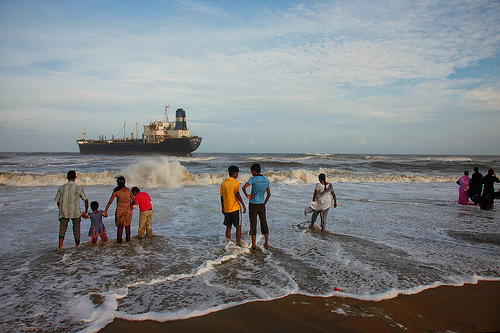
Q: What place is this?
A: It is a shore.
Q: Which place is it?
A: It is a shore.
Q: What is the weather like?
A: It is overcast.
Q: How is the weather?
A: It is overcast.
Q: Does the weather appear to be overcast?
A: Yes, it is overcast.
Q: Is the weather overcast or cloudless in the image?
A: It is overcast.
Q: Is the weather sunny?
A: No, it is overcast.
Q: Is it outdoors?
A: Yes, it is outdoors.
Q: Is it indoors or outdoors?
A: It is outdoors.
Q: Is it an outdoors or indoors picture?
A: It is outdoors.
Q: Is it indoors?
A: No, it is outdoors.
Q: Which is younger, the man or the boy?
A: The boy is younger than the man.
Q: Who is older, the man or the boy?
A: The man is older than the boy.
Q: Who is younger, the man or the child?
A: The child is younger than the man.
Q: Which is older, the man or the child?
A: The man is older than the child.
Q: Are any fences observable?
A: No, there are no fences.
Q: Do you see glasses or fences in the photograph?
A: No, there are no fences or glasses.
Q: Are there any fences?
A: No, there are no fences.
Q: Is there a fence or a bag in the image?
A: No, there are no fences or bags.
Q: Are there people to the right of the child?
A: Yes, there is a person to the right of the child.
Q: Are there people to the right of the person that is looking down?
A: Yes, there is a person to the right of the child.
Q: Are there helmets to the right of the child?
A: No, there is a person to the right of the child.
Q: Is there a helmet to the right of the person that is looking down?
A: No, there is a person to the right of the child.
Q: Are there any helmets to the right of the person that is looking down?
A: No, there is a person to the right of the child.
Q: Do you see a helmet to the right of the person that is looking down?
A: No, there is a person to the right of the child.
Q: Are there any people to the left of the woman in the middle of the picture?
A: Yes, there is a person to the left of the woman.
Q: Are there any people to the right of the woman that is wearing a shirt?
A: No, the person is to the left of the woman.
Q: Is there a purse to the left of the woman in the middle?
A: No, there is a person to the left of the woman.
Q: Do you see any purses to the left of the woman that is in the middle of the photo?
A: No, there is a person to the left of the woman.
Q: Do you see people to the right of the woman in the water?
A: Yes, there is a person to the right of the woman.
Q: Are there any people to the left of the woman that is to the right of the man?
A: No, the person is to the right of the woman.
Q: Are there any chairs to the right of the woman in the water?
A: No, there is a person to the right of the woman.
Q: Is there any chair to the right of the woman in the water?
A: No, there is a person to the right of the woman.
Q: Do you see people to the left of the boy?
A: Yes, there is a person to the left of the boy.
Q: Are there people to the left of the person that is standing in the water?
A: Yes, there is a person to the left of the boy.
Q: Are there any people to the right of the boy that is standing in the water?
A: No, the person is to the left of the boy.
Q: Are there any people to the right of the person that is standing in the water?
A: No, the person is to the left of the boy.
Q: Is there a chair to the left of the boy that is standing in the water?
A: No, there is a person to the left of the boy.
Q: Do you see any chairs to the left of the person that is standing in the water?
A: No, there is a person to the left of the boy.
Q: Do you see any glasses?
A: No, there are no glasses.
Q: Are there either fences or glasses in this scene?
A: No, there are no glasses or fences.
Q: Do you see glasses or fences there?
A: No, there are no glasses or fences.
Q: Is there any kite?
A: No, there are no kites.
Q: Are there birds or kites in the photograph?
A: No, there are no kites or birds.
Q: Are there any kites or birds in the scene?
A: No, there are no kites or birds.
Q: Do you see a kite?
A: No, there are no kites.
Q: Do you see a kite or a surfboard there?
A: No, there are no kites or surfboards.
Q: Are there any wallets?
A: No, there are no wallets.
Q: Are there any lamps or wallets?
A: No, there are no wallets or lamps.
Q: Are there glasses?
A: No, there are no glasses.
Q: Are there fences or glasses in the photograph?
A: No, there are no glasses or fences.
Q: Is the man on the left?
A: Yes, the man is on the left of the image.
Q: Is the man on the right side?
A: No, the man is on the left of the image.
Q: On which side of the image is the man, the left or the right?
A: The man is on the left of the image.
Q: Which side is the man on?
A: The man is on the left of the image.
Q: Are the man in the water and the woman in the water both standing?
A: Yes, both the man and the woman are standing.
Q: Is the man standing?
A: Yes, the man is standing.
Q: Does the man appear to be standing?
A: Yes, the man is standing.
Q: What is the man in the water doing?
A: The man is standing.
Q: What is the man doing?
A: The man is standing.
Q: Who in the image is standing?
A: The man is standing.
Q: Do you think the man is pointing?
A: No, the man is standing.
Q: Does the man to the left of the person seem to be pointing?
A: No, the man is standing.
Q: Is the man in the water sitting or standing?
A: The man is standing.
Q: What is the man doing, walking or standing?
A: The man is standing.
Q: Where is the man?
A: The man is in the water.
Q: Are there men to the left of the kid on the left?
A: Yes, there is a man to the left of the kid.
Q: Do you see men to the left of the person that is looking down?
A: Yes, there is a man to the left of the kid.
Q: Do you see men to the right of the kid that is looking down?
A: No, the man is to the left of the kid.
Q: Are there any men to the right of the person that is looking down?
A: No, the man is to the left of the kid.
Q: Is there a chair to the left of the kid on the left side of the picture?
A: No, there is a man to the left of the child.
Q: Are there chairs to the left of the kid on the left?
A: No, there is a man to the left of the child.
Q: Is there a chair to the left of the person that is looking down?
A: No, there is a man to the left of the child.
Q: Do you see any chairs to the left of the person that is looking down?
A: No, there is a man to the left of the child.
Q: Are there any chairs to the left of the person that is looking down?
A: No, there is a man to the left of the child.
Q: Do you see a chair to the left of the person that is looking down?
A: No, there is a man to the left of the child.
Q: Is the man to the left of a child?
A: Yes, the man is to the left of a child.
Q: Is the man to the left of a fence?
A: No, the man is to the left of a child.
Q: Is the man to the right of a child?
A: No, the man is to the left of a child.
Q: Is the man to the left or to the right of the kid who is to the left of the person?
A: The man is to the left of the child.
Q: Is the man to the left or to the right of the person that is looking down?
A: The man is to the left of the child.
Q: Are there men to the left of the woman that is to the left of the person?
A: Yes, there is a man to the left of the woman.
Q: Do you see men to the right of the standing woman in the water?
A: No, the man is to the left of the woman.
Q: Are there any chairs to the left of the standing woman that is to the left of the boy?
A: No, there is a man to the left of the woman.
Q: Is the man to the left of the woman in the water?
A: Yes, the man is to the left of the woman.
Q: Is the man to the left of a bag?
A: No, the man is to the left of the woman.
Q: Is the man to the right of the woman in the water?
A: No, the man is to the left of the woman.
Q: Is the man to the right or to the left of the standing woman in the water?
A: The man is to the left of the woman.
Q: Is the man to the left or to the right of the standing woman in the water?
A: The man is to the left of the woman.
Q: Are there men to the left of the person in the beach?
A: Yes, there is a man to the left of the person.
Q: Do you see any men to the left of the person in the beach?
A: Yes, there is a man to the left of the person.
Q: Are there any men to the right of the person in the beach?
A: No, the man is to the left of the person.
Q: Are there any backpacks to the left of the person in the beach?
A: No, there is a man to the left of the person.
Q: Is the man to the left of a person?
A: Yes, the man is to the left of a person.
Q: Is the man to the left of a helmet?
A: No, the man is to the left of a person.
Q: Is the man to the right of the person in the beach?
A: No, the man is to the left of the person.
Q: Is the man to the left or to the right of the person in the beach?
A: The man is to the left of the person.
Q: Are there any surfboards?
A: No, there are no surfboards.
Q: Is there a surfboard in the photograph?
A: No, there are no surfboards.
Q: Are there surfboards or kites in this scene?
A: No, there are no surfboards or kites.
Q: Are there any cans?
A: No, there are no cans.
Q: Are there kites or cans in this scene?
A: No, there are no cans or kites.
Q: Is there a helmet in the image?
A: No, there are no helmets.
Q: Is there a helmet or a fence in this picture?
A: No, there are no helmets or fences.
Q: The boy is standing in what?
A: The boy is standing in the water.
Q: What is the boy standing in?
A: The boy is standing in the water.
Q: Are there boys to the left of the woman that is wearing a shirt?
A: Yes, there is a boy to the left of the woman.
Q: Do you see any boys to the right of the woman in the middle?
A: No, the boy is to the left of the woman.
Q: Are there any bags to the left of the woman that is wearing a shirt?
A: No, there is a boy to the left of the woman.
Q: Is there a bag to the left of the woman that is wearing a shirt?
A: No, there is a boy to the left of the woman.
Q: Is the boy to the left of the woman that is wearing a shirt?
A: Yes, the boy is to the left of the woman.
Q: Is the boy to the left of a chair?
A: No, the boy is to the left of the woman.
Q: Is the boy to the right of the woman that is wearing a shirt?
A: No, the boy is to the left of the woman.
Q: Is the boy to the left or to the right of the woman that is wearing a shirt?
A: The boy is to the left of the woman.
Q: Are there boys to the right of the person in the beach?
A: Yes, there is a boy to the right of the person.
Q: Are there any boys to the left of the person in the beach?
A: No, the boy is to the right of the person.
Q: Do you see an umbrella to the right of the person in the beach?
A: No, there is a boy to the right of the person.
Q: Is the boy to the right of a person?
A: Yes, the boy is to the right of a person.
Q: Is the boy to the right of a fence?
A: No, the boy is to the right of a person.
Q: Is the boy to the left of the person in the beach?
A: No, the boy is to the right of the person.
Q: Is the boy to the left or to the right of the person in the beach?
A: The boy is to the right of the person.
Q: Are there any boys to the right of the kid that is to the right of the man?
A: Yes, there is a boy to the right of the child.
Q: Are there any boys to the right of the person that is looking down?
A: Yes, there is a boy to the right of the child.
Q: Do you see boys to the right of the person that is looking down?
A: Yes, there is a boy to the right of the child.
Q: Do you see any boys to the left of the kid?
A: No, the boy is to the right of the kid.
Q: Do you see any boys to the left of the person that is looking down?
A: No, the boy is to the right of the kid.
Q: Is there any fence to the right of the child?
A: No, there is a boy to the right of the child.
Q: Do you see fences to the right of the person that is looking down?
A: No, there is a boy to the right of the child.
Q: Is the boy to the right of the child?
A: Yes, the boy is to the right of the child.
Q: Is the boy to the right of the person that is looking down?
A: Yes, the boy is to the right of the child.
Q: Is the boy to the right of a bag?
A: No, the boy is to the right of the child.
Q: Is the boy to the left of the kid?
A: No, the boy is to the right of the kid.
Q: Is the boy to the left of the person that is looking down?
A: No, the boy is to the right of the kid.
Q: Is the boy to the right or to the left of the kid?
A: The boy is to the right of the kid.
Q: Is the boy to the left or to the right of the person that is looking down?
A: The boy is to the right of the kid.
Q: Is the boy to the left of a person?
A: No, the boy is to the right of a person.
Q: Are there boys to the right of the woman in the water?
A: Yes, there is a boy to the right of the woman.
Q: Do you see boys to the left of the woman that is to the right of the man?
A: No, the boy is to the right of the woman.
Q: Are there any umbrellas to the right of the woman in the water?
A: No, there is a boy to the right of the woman.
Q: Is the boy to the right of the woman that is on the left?
A: Yes, the boy is to the right of the woman.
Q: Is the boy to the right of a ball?
A: No, the boy is to the right of the woman.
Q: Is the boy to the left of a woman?
A: No, the boy is to the right of a woman.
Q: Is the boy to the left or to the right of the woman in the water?
A: The boy is to the right of the woman.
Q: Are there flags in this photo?
A: No, there are no flags.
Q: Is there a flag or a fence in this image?
A: No, there are no flags or fences.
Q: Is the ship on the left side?
A: Yes, the ship is on the left of the image.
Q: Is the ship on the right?
A: No, the ship is on the left of the image.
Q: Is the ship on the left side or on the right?
A: The ship is on the left of the image.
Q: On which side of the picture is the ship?
A: The ship is on the left of the image.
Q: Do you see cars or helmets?
A: No, there are no helmets or cars.